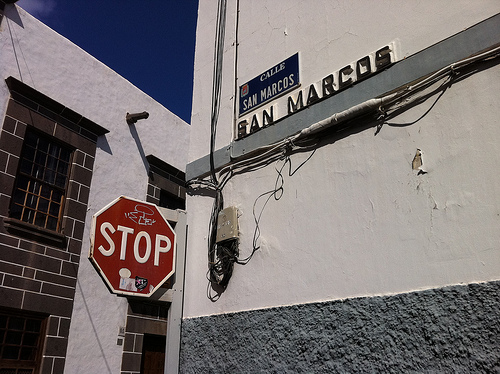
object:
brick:
[72, 150, 85, 167]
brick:
[67, 180, 79, 202]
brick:
[62, 217, 73, 238]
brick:
[60, 261, 78, 279]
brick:
[22, 266, 35, 279]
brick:
[4, 274, 40, 294]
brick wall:
[0, 100, 98, 374]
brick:
[63, 199, 88, 223]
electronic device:
[216, 205, 240, 243]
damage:
[411, 149, 429, 173]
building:
[178, 0, 492, 374]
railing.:
[8, 128, 73, 232]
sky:
[12, 0, 200, 123]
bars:
[56, 192, 63, 232]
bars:
[32, 185, 41, 224]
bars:
[45, 187, 53, 228]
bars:
[20, 181, 30, 221]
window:
[9, 127, 74, 234]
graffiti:
[125, 205, 156, 225]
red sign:
[88, 196, 175, 298]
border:
[187, 0, 226, 180]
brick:
[73, 221, 84, 242]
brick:
[40, 282, 74, 300]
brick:
[22, 291, 74, 316]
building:
[0, 0, 190, 374]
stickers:
[119, 278, 137, 292]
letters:
[237, 45, 393, 139]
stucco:
[178, 280, 500, 374]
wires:
[184, 38, 500, 302]